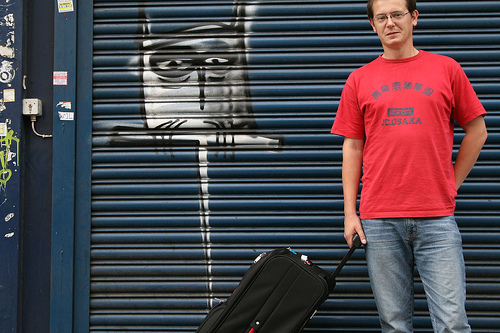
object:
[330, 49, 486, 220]
t-shirt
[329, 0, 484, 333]
man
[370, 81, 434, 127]
writing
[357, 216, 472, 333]
jeans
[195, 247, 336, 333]
suitcase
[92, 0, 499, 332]
garage door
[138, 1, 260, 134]
owl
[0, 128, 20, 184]
paint splatters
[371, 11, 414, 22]
glasses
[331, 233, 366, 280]
handle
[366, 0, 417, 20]
hair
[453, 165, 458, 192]
hand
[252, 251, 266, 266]
lock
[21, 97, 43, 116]
electrical switch